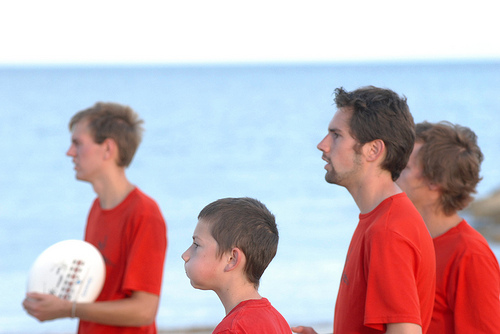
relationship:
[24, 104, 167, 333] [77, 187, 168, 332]
male wearing shirt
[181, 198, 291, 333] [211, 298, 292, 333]
male wearing shirt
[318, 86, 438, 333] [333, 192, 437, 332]
male wearing shirt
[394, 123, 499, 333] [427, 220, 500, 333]
male wearing shirt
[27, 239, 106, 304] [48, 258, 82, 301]
frisbee with lettering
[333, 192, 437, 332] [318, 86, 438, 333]
shirt of male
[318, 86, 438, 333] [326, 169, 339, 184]
male with goatee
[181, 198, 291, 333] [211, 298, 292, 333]
male with shirt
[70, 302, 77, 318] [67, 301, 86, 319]
watch worn on wrist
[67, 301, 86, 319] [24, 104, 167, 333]
wrist of male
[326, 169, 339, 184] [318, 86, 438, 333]
goatee of male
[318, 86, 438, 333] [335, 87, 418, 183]
male with hair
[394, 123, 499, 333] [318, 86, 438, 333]
male obscured by male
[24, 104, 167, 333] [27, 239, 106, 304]
male holding frisbee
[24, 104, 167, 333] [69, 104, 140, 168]
male has hair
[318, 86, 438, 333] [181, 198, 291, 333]
male to left of male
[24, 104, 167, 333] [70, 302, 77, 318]
male wears watch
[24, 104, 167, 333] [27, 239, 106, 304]
male standing with frisbee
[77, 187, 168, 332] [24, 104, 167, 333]
shirt worn on male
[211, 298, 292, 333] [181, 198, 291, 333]
shirt worn on male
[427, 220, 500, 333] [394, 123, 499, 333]
shirt worn on male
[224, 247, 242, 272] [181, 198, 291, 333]
ear of male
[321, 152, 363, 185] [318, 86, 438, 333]
facial hair growing on male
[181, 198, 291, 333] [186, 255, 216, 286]
male has cheek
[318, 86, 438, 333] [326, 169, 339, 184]
male has goatee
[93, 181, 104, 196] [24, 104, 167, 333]
adam's apple of male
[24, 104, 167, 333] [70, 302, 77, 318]
male has watch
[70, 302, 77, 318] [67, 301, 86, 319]
watch on wrist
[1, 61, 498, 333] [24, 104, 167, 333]
water on side of male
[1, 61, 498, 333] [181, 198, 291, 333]
water on side of male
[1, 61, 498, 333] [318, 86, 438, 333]
water on side of male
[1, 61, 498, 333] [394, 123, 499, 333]
water on side of male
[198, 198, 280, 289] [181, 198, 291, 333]
hair of male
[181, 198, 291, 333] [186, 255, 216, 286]
male puffing out cheek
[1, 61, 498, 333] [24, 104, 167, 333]
water next to male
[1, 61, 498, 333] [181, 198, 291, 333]
water next to male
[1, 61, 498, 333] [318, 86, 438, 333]
water next to male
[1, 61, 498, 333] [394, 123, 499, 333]
water next to male